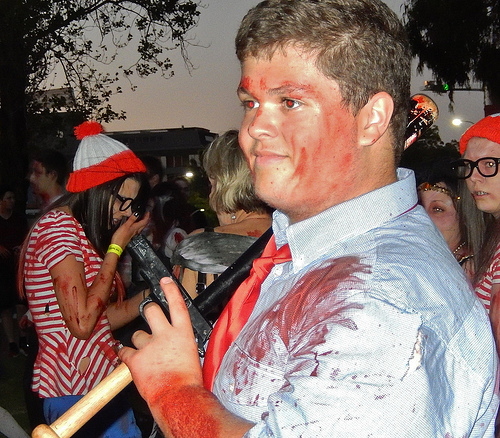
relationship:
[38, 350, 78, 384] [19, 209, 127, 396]
stripe on shirt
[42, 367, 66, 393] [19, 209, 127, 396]
stripe on shirt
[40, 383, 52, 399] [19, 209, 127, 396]
stripe on shirt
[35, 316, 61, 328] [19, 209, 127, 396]
stripe on shirt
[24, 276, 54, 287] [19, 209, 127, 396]
stripe on shirt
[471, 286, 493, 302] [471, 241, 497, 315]
stripe on shirt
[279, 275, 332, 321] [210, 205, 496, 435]
blood on shirt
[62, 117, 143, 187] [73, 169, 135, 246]
hat on head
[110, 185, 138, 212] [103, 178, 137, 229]
glasses on face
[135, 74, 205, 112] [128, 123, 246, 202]
sky above land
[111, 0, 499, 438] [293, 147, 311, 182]
man with blood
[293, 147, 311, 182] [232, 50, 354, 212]
blood on face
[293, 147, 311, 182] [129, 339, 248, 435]
blood on arms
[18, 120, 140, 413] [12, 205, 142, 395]
woman wearing striped shirt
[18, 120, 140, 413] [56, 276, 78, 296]
woman with blood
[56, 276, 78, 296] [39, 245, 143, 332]
blood on arms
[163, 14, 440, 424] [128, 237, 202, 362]
man holding gun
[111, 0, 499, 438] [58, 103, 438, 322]
man holding bat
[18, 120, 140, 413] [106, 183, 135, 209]
woman wearing eyeglasses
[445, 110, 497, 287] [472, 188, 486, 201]
woman wearing teeth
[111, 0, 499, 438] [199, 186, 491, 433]
man in shirt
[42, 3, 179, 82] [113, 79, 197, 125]
branches in sunset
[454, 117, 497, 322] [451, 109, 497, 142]
girl in beanie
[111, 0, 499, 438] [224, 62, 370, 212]
man with red paint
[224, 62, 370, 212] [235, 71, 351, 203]
red paint on face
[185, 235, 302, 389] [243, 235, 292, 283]
red tie with loose knot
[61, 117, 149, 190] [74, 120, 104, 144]
cap with pom pom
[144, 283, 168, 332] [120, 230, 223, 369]
finger in hand gun